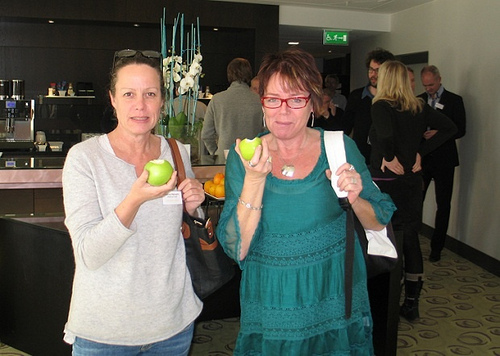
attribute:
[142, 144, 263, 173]
apples — green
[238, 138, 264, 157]
apple — green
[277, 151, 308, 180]
necklace — shiny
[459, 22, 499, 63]
wall — white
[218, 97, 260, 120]
sweater — gray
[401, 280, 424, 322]
boots — black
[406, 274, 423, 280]
socks — gray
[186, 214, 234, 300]
purse — black, brown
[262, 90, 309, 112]
glasses — red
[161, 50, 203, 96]
flowers — white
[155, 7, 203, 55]
sticks — blue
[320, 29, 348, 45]
sign — green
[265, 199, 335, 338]
dress — turquoise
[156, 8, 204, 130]
floral arrangement — tall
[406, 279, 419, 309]
boot — black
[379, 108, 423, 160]
suit — black